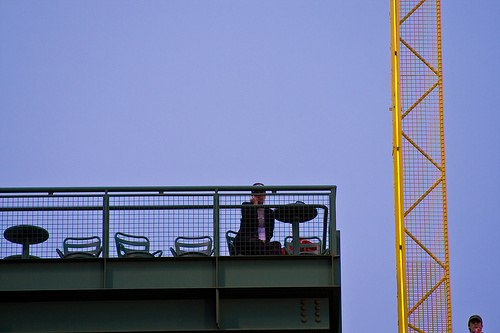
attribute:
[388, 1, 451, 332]
tower — yellow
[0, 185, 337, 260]
fence — green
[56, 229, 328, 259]
seats — green, empty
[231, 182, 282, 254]
person — sitting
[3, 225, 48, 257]
table — green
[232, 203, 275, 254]
sweater — black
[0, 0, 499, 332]
sky — blue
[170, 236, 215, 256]
chair — green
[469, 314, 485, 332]
man — sitting